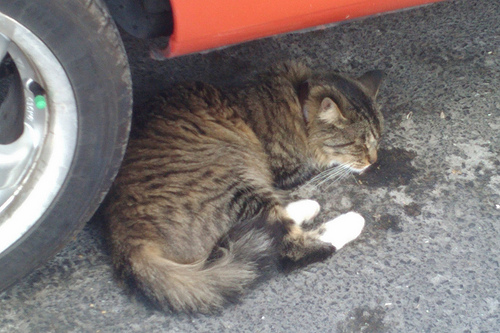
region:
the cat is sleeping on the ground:
[107, 40, 459, 310]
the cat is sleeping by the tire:
[79, 55, 431, 309]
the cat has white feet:
[277, 165, 430, 292]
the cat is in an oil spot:
[71, 75, 453, 177]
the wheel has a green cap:
[0, 46, 102, 211]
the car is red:
[140, 3, 422, 107]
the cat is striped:
[137, 165, 328, 285]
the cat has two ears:
[302, 68, 428, 153]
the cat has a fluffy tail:
[108, 233, 344, 318]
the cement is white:
[424, 105, 496, 245]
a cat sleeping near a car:
[3, 3, 444, 331]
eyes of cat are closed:
[249, 49, 400, 191]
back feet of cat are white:
[282, 196, 373, 248]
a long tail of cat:
[119, 228, 290, 321]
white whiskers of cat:
[293, 150, 382, 196]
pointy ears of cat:
[311, 60, 391, 130]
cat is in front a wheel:
[0, 2, 402, 322]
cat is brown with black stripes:
[107, 48, 401, 315]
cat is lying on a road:
[107, 57, 497, 330]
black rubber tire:
[0, 2, 138, 299]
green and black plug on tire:
[27, 79, 49, 110]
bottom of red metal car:
[140, 2, 499, 60]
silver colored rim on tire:
[1, 9, 84, 253]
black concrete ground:
[0, 1, 499, 331]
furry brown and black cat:
[98, 58, 388, 318]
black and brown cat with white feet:
[90, 52, 393, 317]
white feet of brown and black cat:
[278, 192, 368, 252]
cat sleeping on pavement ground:
[87, 57, 379, 314]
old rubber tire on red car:
[0, 2, 143, 299]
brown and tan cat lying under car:
[85, 58, 415, 328]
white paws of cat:
[277, 193, 369, 253]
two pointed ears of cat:
[304, 64, 391, 129]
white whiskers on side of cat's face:
[286, 156, 362, 203]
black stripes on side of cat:
[134, 105, 237, 225]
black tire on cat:
[0, 0, 140, 314]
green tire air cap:
[27, 91, 52, 117]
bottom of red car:
[111, 2, 431, 60]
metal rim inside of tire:
[0, 14, 82, 274]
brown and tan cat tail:
[121, 225, 280, 313]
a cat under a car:
[34, 19, 466, 296]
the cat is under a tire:
[19, 12, 456, 282]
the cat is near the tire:
[23, 19, 436, 324]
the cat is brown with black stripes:
[144, 69, 402, 286]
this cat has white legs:
[259, 195, 371, 260]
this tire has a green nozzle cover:
[18, 11, 59, 148]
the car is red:
[159, 7, 389, 60]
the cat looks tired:
[167, 76, 415, 278]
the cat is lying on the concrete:
[135, 76, 412, 271]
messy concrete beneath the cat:
[347, 41, 481, 308]